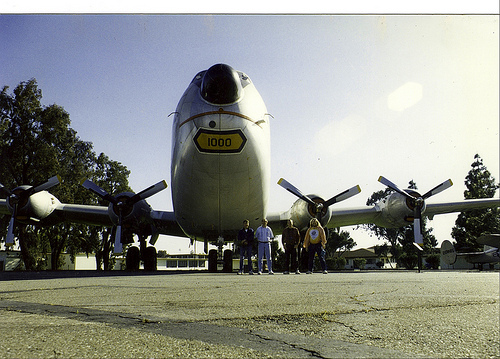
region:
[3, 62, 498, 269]
silver plane on runway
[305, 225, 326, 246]
yellow and white shirt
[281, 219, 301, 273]
man wearing plaid shirt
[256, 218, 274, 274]
man wearing white shirt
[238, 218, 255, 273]
man wearing black jacket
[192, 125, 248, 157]
yellow and black plaque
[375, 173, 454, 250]
metal propeller on wing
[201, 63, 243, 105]
black nose on plane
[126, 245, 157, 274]
black tires on plane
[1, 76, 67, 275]
tree with green leaves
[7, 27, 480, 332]
a large plane for flying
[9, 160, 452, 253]
this plane has four engines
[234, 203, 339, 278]
these men are near the plane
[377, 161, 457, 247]
a propeller on the plane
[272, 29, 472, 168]
a hazy sky above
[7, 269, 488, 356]
a cracked concrete runway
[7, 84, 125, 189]
trees near the plane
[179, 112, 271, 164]
a marker on the plane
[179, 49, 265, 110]
the nose of the plane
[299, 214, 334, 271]
this guy is wearing a yellow sweatshirt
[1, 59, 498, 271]
Airplane parked on tarmac.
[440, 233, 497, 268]
Small airplane parked in background.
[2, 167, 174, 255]
Propellers in front of two engines on airplane's wing.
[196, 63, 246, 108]
Nose cone on airplane.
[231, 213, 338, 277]
Men standing in front of plane.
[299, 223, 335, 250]
Man dressed in yellow sweatshirt.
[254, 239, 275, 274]
Man dressed in light blue pants.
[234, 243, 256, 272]
Man dressed in blue jeans.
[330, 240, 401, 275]
House in background behind airplane.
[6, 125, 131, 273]
Trees growing behind airplane.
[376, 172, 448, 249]
airplane engine with propeller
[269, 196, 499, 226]
airplane's port side wing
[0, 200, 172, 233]
airplane's starboard side wing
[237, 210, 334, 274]
men standing in a row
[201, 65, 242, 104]
black nose of an airplane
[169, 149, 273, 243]
fuselage of an airplane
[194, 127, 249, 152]
sign reading 1000 painted in black and yellow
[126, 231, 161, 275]
landing gear of airplane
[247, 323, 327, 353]
crack in the black asphalt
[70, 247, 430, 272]
buildings behind the airplane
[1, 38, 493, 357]
A big silver color airplane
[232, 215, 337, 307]
Four men are standing in front of the plane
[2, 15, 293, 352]
Tree is behind the airplane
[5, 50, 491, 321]
airplane is on the green flooring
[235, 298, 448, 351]
Lots of cracks on the ground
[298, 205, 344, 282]
A man wearing a yellow color shirt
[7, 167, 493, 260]
Airplane's four engines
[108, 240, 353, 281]
Air plane with six wheels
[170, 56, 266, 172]
Air plane's cabin is in black color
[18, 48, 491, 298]
Airplane stands between the trees